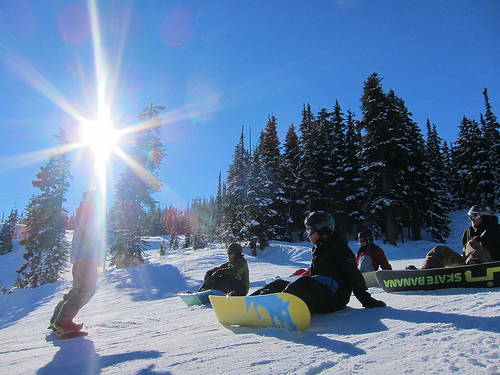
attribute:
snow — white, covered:
[8, 215, 490, 367]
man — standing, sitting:
[59, 231, 111, 334]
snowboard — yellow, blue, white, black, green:
[51, 314, 84, 344]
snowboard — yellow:
[213, 289, 313, 332]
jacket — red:
[72, 206, 106, 281]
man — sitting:
[198, 257, 256, 307]